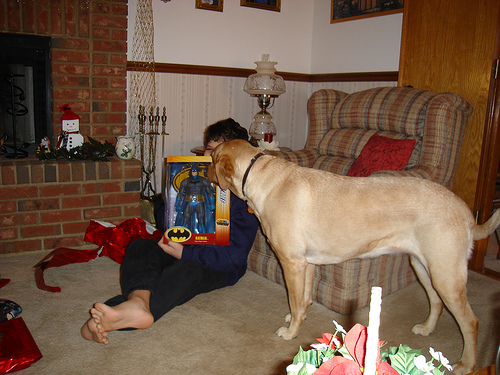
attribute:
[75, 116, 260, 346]
boy — sitting, present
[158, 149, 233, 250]
present — batman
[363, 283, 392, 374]
handle — present, white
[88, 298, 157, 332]
foot — present, bare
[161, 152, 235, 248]
batman — present, muscular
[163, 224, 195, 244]
logo — black, yellow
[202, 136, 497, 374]
dog — large, beige, tan, present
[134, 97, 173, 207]
tools — present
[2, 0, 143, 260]
fireplace — red, brick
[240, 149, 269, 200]
collar — black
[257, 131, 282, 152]
candle —  visible.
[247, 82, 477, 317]
chair — rust, brown, plaid, heavy, striped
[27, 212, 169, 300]
paper — red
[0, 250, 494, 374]
floor — tan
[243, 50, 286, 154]
lamp — present, domed, old fashioned, old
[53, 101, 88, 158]
snowman —  decoration.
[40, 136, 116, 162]
branch —  decoration.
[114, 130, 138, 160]
vase —  decoration.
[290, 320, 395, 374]
flower — present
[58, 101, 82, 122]
hat — red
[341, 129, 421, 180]
pillow — red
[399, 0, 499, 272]
door — wooden